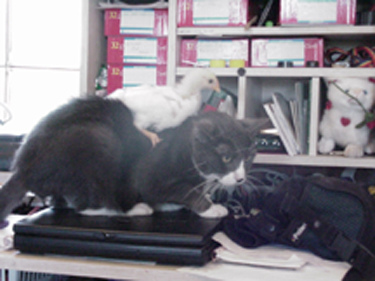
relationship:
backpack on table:
[228, 168, 375, 276] [2, 210, 359, 281]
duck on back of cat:
[97, 67, 221, 151] [1, 94, 265, 232]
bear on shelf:
[317, 78, 375, 162] [310, 74, 375, 169]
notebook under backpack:
[209, 229, 314, 271] [228, 168, 375, 276]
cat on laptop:
[1, 94, 265, 232] [10, 196, 223, 264]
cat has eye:
[1, 94, 265, 232] [220, 152, 234, 168]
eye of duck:
[206, 77, 214, 85] [97, 67, 221, 151]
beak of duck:
[214, 85, 221, 93] [97, 67, 221, 151]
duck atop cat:
[97, 67, 221, 151] [1, 94, 265, 232]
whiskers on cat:
[186, 172, 268, 201] [1, 94, 265, 232]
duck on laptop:
[97, 67, 221, 151] [10, 196, 223, 264]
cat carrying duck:
[1, 94, 265, 232] [97, 67, 221, 151]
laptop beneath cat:
[10, 196, 223, 264] [1, 94, 265, 232]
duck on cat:
[97, 67, 221, 151] [1, 94, 265, 232]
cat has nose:
[1, 94, 265, 232] [236, 176, 247, 186]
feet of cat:
[200, 202, 228, 220] [1, 94, 265, 232]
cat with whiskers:
[1, 94, 265, 232] [186, 172, 268, 201]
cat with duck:
[1, 94, 265, 232] [97, 67, 221, 151]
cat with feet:
[1, 94, 265, 232] [200, 202, 228, 220]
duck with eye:
[97, 67, 221, 151] [206, 77, 214, 85]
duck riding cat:
[97, 67, 221, 151] [1, 94, 265, 232]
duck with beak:
[97, 67, 221, 151] [214, 85, 221, 93]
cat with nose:
[1, 94, 265, 232] [236, 176, 247, 186]